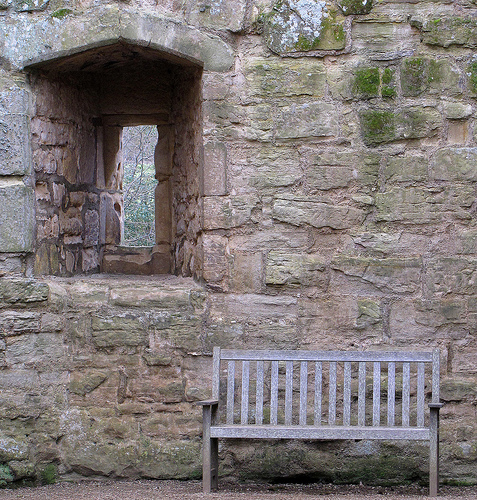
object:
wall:
[0, 0, 476, 485]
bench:
[196, 344, 443, 495]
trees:
[103, 114, 172, 272]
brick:
[202, 141, 225, 194]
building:
[1, 0, 475, 497]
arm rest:
[198, 397, 217, 405]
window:
[118, 119, 158, 249]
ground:
[0, 480, 476, 500]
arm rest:
[427, 400, 442, 409]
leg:
[426, 405, 442, 497]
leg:
[201, 407, 217, 491]